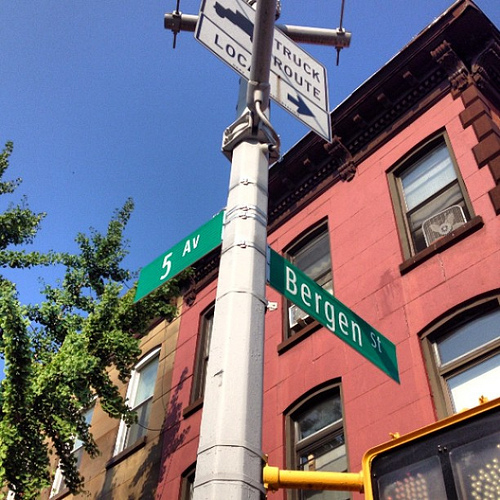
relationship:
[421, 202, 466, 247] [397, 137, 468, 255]
fan in window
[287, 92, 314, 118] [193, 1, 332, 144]
arrow on sign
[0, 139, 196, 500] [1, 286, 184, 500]
tree in front of building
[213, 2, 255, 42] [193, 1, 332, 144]
truck graphic on sign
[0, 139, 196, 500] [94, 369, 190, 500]
tree has shadow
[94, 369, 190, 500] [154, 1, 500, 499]
shadow on building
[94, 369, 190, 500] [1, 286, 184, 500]
shadow on building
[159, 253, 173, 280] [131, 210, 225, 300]
5 on street sign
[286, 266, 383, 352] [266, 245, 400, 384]
bergen st on street sign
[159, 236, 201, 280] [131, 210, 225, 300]
5 av on street sign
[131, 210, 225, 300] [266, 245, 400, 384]
street sign next to street sign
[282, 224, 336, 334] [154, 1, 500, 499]
window in building